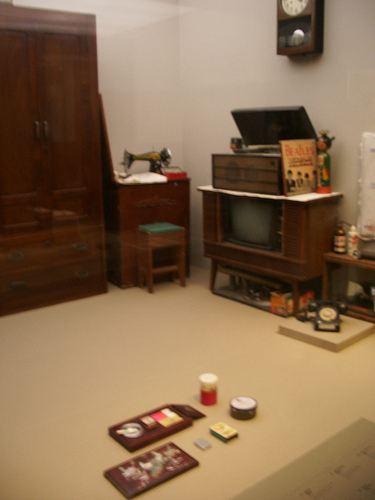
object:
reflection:
[0, 216, 110, 317]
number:
[287, 5, 294, 15]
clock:
[279, 1, 309, 19]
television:
[218, 192, 283, 255]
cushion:
[137, 220, 187, 236]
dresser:
[103, 175, 192, 290]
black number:
[294, 6, 301, 14]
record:
[278, 138, 320, 199]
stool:
[133, 218, 188, 294]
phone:
[312, 303, 341, 333]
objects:
[106, 401, 207, 454]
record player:
[210, 104, 320, 197]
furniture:
[194, 183, 344, 320]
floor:
[0, 265, 375, 498]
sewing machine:
[118, 145, 173, 176]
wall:
[10, 1, 375, 275]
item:
[101, 438, 202, 500]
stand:
[318, 249, 374, 328]